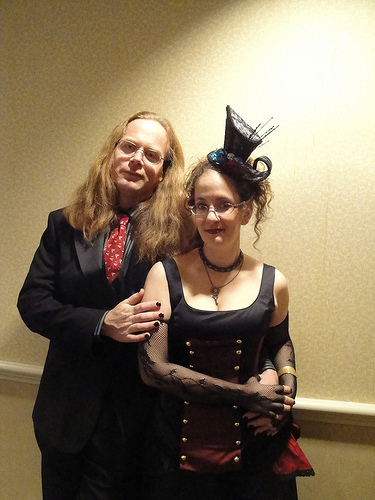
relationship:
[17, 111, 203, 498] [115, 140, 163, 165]
man has on glasses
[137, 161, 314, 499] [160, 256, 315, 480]
woman has on a top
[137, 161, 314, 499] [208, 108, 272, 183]
woman has a hat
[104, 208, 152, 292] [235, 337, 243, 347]
shirt has a button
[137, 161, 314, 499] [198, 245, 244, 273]
woman has a choker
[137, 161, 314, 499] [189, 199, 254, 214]
woman has on glasses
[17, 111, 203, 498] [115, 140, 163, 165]
man has glasses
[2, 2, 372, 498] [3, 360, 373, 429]
wall has moulding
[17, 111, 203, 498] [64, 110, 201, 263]
man has hair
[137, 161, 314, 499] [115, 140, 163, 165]
woman has on glasses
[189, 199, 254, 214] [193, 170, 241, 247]
glasses are on a face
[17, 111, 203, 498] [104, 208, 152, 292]
man has on a shirt